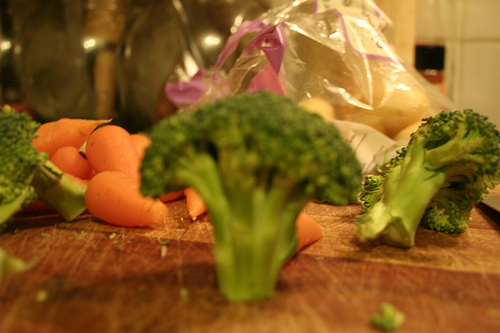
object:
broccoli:
[138, 90, 366, 302]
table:
[0, 197, 499, 331]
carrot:
[85, 170, 169, 227]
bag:
[163, 0, 459, 140]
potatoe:
[337, 66, 429, 137]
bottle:
[413, 41, 447, 93]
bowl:
[115, 0, 239, 123]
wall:
[414, 0, 498, 106]